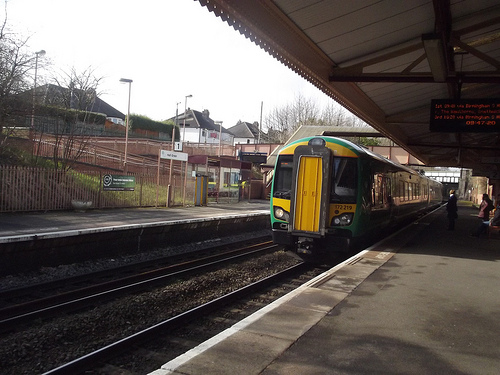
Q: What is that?
A: A train.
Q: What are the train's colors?
A: Green and yellow.